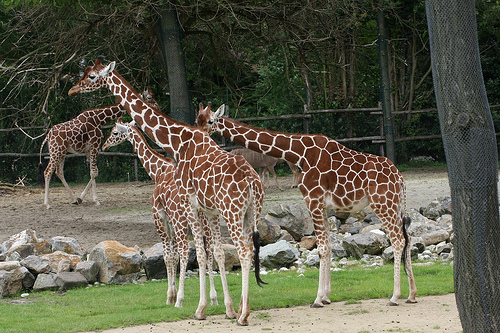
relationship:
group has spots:
[184, 99, 416, 311] [186, 162, 232, 238]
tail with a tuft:
[394, 182, 418, 279] [397, 210, 412, 274]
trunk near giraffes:
[421, 0, 500, 333] [39, 57, 414, 319]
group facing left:
[184, 99, 416, 311] [60, 242, 114, 325]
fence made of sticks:
[293, 93, 457, 173] [339, 92, 402, 155]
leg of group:
[369, 189, 409, 309] [184, 99, 416, 311]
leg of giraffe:
[304, 197, 343, 310] [234, 115, 394, 222]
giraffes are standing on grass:
[52, 41, 465, 321] [59, 280, 174, 323]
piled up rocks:
[4, 220, 99, 311] [27, 227, 134, 287]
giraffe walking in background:
[32, 87, 184, 209] [41, 213, 465, 273]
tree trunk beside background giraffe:
[12, 78, 32, 221] [40, 92, 159, 206]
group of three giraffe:
[106, 157, 391, 274] [99, 119, 219, 306]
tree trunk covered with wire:
[32, 97, 42, 204] [28, 241, 90, 293]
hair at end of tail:
[254, 232, 264, 317] [249, 224, 280, 285]